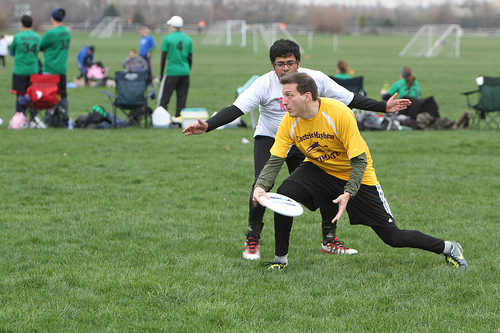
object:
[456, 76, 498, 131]
chair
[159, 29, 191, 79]
shirt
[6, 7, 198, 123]
people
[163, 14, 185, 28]
hat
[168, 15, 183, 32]
head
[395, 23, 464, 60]
soccer goal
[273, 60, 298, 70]
glasses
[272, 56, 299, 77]
face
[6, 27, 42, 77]
shirt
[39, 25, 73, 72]
shirt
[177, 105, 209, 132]
cooler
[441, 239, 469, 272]
shoe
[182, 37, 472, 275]
people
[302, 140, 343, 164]
logo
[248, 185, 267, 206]
hand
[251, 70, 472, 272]
man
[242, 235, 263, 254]
laces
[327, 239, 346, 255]
laces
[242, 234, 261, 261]
sneaker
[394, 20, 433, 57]
goal post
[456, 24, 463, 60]
goal post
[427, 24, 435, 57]
goal post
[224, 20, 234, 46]
goal post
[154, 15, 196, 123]
man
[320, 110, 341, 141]
stripe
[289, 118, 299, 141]
stripe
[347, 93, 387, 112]
shirt sleeve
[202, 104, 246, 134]
shirt sleeve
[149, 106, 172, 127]
cooler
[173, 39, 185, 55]
number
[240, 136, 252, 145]
paper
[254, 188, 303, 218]
frisbee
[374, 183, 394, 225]
stripe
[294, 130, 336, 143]
word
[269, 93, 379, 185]
shirt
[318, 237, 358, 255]
sneaker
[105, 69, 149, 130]
chair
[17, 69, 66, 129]
chair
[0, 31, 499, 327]
field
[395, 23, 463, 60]
soccer net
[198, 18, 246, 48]
soccer net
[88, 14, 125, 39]
soccer net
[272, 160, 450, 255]
pants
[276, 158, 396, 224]
shorts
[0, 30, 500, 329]
grass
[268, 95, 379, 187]
pullover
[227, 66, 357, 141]
shirt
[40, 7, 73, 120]
man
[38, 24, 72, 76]
jersey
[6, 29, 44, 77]
jersey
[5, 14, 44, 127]
man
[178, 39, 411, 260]
man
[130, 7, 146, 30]
pine tree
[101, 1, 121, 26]
pine tree